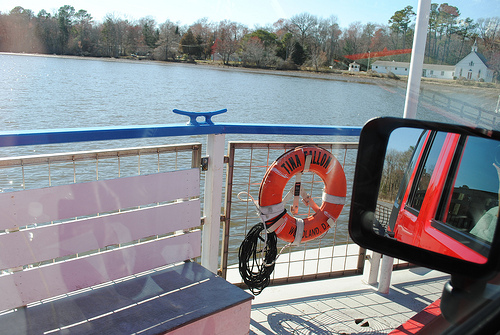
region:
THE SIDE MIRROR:
[346, 112, 499, 283]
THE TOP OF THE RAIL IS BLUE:
[0, 97, 380, 149]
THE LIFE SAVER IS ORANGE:
[257, 142, 347, 251]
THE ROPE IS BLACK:
[226, 213, 291, 295]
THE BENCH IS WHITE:
[0, 161, 253, 333]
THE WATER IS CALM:
[1, 52, 499, 274]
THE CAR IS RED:
[367, 114, 499, 334]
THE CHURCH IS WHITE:
[370, 37, 495, 80]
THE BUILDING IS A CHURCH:
[372, 35, 493, 95]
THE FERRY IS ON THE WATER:
[1, 0, 498, 332]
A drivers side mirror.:
[349, 117, 498, 284]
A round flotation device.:
[259, 142, 346, 249]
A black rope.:
[239, 222, 277, 293]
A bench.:
[1, 168, 248, 333]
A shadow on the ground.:
[243, 280, 445, 331]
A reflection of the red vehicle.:
[390, 128, 497, 263]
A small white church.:
[455, 32, 494, 86]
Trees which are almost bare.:
[2, 4, 497, 81]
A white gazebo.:
[346, 59, 363, 77]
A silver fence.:
[3, 140, 408, 276]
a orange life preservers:
[247, 130, 357, 260]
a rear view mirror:
[346, 100, 481, 290]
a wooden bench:
[62, 161, 248, 322]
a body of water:
[52, 68, 305, 139]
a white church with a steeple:
[370, 31, 486, 88]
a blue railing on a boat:
[35, 107, 370, 177]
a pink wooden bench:
[55, 150, 210, 331]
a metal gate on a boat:
[220, 135, 350, 302]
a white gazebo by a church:
[337, 53, 485, 92]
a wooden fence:
[386, 67, 474, 101]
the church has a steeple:
[465, 34, 481, 65]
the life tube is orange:
[261, 146, 363, 233]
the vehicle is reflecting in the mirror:
[405, 145, 469, 206]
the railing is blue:
[39, 124, 133, 143]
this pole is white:
[399, 24, 434, 105]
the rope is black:
[239, 236, 289, 286]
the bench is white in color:
[39, 192, 130, 269]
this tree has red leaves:
[206, 29, 230, 60]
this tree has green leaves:
[279, 27, 302, 63]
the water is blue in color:
[43, 65, 142, 108]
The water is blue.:
[26, 80, 121, 113]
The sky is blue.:
[185, 1, 294, 13]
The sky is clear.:
[208, 2, 291, 14]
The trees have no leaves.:
[83, 2, 145, 47]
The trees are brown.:
[95, 16, 144, 44]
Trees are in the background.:
[92, 20, 154, 56]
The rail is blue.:
[16, 102, 191, 144]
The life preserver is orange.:
[246, 137, 348, 254]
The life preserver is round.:
[247, 130, 342, 252]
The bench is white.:
[6, 163, 252, 326]